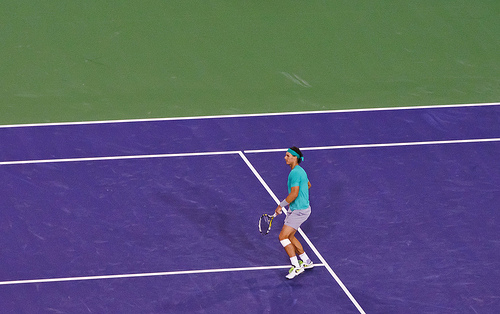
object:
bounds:
[0, 0, 499, 125]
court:
[0, 0, 499, 314]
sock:
[290, 252, 312, 269]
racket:
[258, 211, 282, 236]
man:
[275, 146, 314, 279]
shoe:
[285, 260, 313, 280]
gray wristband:
[279, 199, 289, 208]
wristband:
[278, 205, 288, 212]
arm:
[279, 176, 300, 206]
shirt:
[287, 165, 310, 212]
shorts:
[284, 205, 312, 230]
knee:
[279, 232, 290, 243]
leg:
[279, 211, 309, 267]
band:
[280, 238, 291, 247]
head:
[284, 146, 303, 165]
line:
[0, 102, 500, 127]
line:
[0, 138, 500, 166]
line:
[0, 263, 324, 284]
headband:
[287, 148, 304, 162]